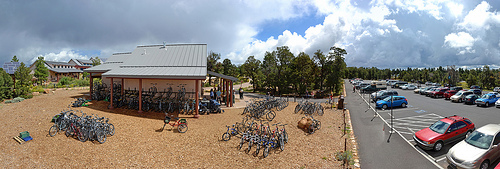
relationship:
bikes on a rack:
[261, 135, 276, 158] [221, 116, 292, 158]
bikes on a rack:
[273, 123, 288, 150] [221, 116, 292, 158]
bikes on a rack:
[220, 120, 236, 140] [221, 116, 292, 158]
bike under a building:
[144, 83, 164, 105] [81, 41, 239, 118]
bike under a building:
[159, 112, 188, 133] [81, 41, 239, 118]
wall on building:
[112, 45, 218, 85] [90, 70, 255, 139]